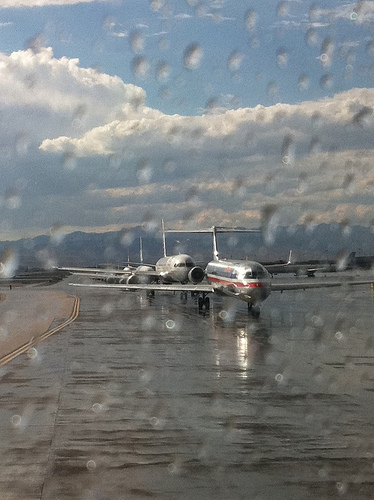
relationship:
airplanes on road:
[47, 217, 370, 322] [7, 266, 374, 498]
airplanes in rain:
[47, 217, 370, 322] [1, 1, 374, 500]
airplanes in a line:
[47, 217, 370, 322] [52, 219, 370, 333]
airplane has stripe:
[68, 218, 369, 332] [205, 272, 265, 293]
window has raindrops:
[2, 0, 374, 497] [126, 27, 210, 88]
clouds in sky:
[2, 45, 372, 163] [1, 1, 374, 235]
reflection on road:
[207, 319, 267, 368] [7, 266, 374, 498]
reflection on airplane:
[222, 260, 255, 281] [68, 218, 369, 332]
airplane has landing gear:
[68, 218, 369, 332] [196, 295, 263, 316]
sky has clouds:
[1, 1, 374, 235] [2, 45, 372, 163]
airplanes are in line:
[47, 217, 370, 322] [52, 219, 370, 333]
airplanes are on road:
[47, 217, 370, 322] [7, 266, 374, 498]